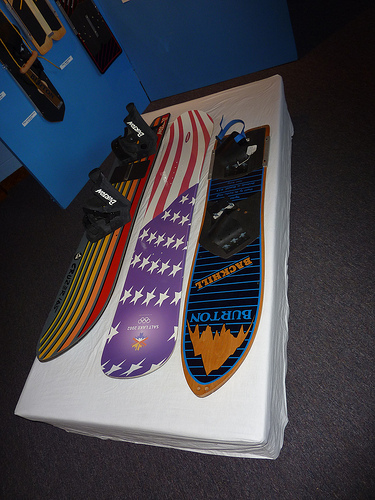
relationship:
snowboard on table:
[180, 124, 270, 399] [15, 74, 296, 462]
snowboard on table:
[101, 110, 215, 384] [15, 74, 296, 462]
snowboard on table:
[36, 110, 172, 370] [15, 74, 296, 462]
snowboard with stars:
[101, 110, 215, 384] [100, 195, 197, 378]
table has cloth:
[15, 74, 296, 462] [13, 74, 294, 461]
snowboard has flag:
[101, 110, 215, 384] [102, 109, 216, 381]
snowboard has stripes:
[101, 110, 215, 384] [142, 109, 213, 228]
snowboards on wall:
[2, 2, 123, 128] [0, 1, 299, 209]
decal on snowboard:
[184, 320, 255, 374] [180, 124, 270, 399]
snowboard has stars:
[101, 110, 215, 384] [100, 195, 197, 378]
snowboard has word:
[180, 124, 270, 399] [196, 255, 252, 293]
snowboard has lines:
[36, 110, 172, 370] [36, 113, 170, 364]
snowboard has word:
[36, 110, 172, 370] [96, 189, 116, 208]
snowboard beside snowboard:
[101, 110, 215, 384] [180, 124, 270, 399]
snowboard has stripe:
[36, 110, 172, 370] [74, 116, 162, 343]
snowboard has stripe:
[36, 110, 172, 370] [55, 115, 164, 353]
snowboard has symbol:
[101, 110, 215, 384] [135, 314, 153, 328]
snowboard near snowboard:
[180, 124, 270, 399] [101, 110, 215, 384]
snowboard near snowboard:
[101, 110, 215, 384] [36, 110, 172, 370]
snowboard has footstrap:
[180, 124, 270, 399] [216, 116, 251, 148]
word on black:
[96, 189, 116, 208] [83, 168, 132, 242]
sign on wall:
[59, 56, 74, 70] [0, 1, 299, 209]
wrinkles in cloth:
[205, 94, 259, 116] [13, 74, 294, 461]